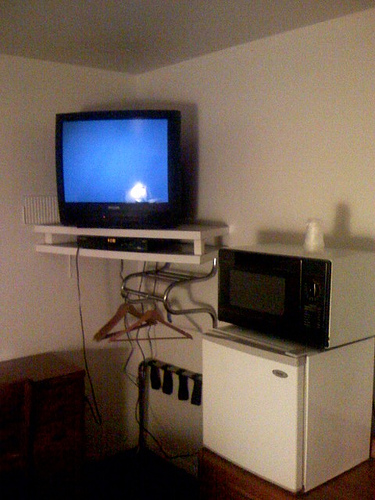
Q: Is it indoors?
A: Yes, it is indoors.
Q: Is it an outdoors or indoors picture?
A: It is indoors.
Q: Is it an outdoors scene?
A: No, it is indoors.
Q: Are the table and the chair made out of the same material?
A: Yes, both the table and the chair are made of wood.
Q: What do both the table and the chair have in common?
A: The material, both the table and the chair are wooden.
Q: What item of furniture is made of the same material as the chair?
A: The table is made of the same material as the chair.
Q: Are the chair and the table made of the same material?
A: Yes, both the chair and the table are made of wood.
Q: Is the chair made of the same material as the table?
A: Yes, both the chair and the table are made of wood.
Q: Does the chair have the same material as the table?
A: Yes, both the chair and the table are made of wood.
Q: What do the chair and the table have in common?
A: The material, both the chair and the table are wooden.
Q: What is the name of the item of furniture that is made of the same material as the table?
A: The piece of furniture is a chair.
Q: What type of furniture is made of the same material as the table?
A: The chair is made of the same material as the table.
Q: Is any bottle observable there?
A: No, there are no bottles.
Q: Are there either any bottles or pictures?
A: No, there are no bottles or pictures.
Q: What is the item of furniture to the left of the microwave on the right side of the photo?
A: The piece of furniture is a shelf.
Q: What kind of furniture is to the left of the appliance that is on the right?
A: The piece of furniture is a shelf.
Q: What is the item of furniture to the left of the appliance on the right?
A: The piece of furniture is a shelf.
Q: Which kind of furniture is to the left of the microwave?
A: The piece of furniture is a shelf.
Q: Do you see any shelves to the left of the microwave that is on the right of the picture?
A: Yes, there is a shelf to the left of the microwave.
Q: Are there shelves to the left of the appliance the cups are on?
A: Yes, there is a shelf to the left of the microwave.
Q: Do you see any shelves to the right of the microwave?
A: No, the shelf is to the left of the microwave.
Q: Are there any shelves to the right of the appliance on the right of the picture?
A: No, the shelf is to the left of the microwave.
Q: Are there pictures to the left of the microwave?
A: No, there is a shelf to the left of the microwave.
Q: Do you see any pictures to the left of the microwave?
A: No, there is a shelf to the left of the microwave.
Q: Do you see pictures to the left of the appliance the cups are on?
A: No, there is a shelf to the left of the microwave.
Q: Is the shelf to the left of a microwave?
A: Yes, the shelf is to the left of a microwave.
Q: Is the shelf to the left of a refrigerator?
A: No, the shelf is to the left of a microwave.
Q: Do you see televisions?
A: Yes, there is a television.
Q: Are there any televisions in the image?
A: Yes, there is a television.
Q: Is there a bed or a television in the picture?
A: Yes, there is a television.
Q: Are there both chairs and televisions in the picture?
A: Yes, there are both a television and a chair.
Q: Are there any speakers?
A: No, there are no speakers.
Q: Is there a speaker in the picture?
A: No, there are no speakers.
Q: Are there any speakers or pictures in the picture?
A: No, there are no speakers or pictures.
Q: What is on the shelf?
A: The television is on the shelf.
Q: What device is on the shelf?
A: The device is a television.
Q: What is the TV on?
A: The TV is on the shelf.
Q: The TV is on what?
A: The TV is on the shelf.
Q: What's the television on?
A: The TV is on the shelf.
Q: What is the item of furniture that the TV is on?
A: The piece of furniture is a shelf.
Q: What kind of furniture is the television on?
A: The TV is on the shelf.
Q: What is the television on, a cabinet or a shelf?
A: The television is on a shelf.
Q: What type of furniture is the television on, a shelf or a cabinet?
A: The television is on a shelf.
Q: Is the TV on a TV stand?
A: No, the TV is on the shelf.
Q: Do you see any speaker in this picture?
A: No, there are no speakers.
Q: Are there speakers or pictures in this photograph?
A: No, there are no speakers or pictures.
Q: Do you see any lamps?
A: No, there are no lamps.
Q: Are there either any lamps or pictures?
A: No, there are no lamps or pictures.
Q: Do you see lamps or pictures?
A: No, there are no lamps or pictures.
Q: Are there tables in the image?
A: Yes, there is a table.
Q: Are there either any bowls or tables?
A: Yes, there is a table.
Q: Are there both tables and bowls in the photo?
A: No, there is a table but no bowls.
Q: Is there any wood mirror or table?
A: Yes, there is a wood table.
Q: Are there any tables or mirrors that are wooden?
A: Yes, the table is wooden.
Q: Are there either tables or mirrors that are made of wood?
A: Yes, the table is made of wood.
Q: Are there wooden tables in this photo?
A: Yes, there is a wood table.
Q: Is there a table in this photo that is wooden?
A: Yes, there is a table that is wooden.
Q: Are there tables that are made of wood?
A: Yes, there is a table that is made of wood.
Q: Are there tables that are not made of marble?
A: Yes, there is a table that is made of wood.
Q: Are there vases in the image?
A: No, there are no vases.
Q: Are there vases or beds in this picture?
A: No, there are no vases or beds.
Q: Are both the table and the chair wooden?
A: Yes, both the table and the chair are wooden.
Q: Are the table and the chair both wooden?
A: Yes, both the table and the chair are wooden.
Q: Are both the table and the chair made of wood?
A: Yes, both the table and the chair are made of wood.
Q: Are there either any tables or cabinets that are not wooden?
A: No, there is a table but it is wooden.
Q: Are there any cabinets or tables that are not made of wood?
A: No, there is a table but it is made of wood.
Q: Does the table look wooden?
A: Yes, the table is wooden.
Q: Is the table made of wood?
A: Yes, the table is made of wood.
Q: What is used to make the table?
A: The table is made of wood.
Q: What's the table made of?
A: The table is made of wood.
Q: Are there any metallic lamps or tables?
A: No, there is a table but it is wooden.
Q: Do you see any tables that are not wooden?
A: No, there is a table but it is wooden.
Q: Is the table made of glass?
A: No, the table is made of wood.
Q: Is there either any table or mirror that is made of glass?
A: No, there is a table but it is made of wood.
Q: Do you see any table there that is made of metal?
A: No, there is a table but it is made of wood.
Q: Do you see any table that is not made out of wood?
A: No, there is a table but it is made of wood.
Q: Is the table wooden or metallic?
A: The table is wooden.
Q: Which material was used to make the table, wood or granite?
A: The table is made of wood.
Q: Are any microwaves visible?
A: Yes, there is a microwave.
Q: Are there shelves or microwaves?
A: Yes, there is a microwave.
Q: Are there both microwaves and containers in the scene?
A: No, there is a microwave but no containers.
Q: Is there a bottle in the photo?
A: No, there are no bottles.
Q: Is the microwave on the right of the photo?
A: Yes, the microwave is on the right of the image.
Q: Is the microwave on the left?
A: No, the microwave is on the right of the image.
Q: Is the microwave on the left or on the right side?
A: The microwave is on the right of the image.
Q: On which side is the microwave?
A: The microwave is on the right of the image.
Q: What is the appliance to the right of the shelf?
A: The appliance is a microwave.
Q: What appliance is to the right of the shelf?
A: The appliance is a microwave.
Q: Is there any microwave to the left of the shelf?
A: No, the microwave is to the right of the shelf.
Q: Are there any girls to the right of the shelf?
A: No, there is a microwave to the right of the shelf.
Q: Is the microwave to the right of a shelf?
A: Yes, the microwave is to the right of a shelf.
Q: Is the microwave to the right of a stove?
A: No, the microwave is to the right of a shelf.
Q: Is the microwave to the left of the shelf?
A: No, the microwave is to the right of the shelf.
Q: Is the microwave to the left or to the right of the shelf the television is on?
A: The microwave is to the right of the shelf.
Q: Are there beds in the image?
A: No, there are no beds.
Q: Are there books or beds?
A: No, there are no beds or books.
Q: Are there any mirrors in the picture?
A: No, there are no mirrors.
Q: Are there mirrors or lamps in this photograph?
A: No, there are no mirrors or lamps.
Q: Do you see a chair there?
A: Yes, there is a chair.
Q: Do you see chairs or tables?
A: Yes, there is a chair.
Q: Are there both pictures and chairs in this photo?
A: No, there is a chair but no pictures.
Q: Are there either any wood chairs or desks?
A: Yes, there is a wood chair.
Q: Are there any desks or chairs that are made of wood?
A: Yes, the chair is made of wood.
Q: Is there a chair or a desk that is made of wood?
A: Yes, the chair is made of wood.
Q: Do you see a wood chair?
A: Yes, there is a chair that is made of wood.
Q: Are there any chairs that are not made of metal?
A: Yes, there is a chair that is made of wood.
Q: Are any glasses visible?
A: No, there are no glasses.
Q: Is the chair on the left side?
A: Yes, the chair is on the left of the image.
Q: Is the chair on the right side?
A: No, the chair is on the left of the image.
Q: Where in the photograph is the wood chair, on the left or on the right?
A: The chair is on the left of the image.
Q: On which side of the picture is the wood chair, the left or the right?
A: The chair is on the left of the image.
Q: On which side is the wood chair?
A: The chair is on the left of the image.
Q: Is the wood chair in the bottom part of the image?
A: Yes, the chair is in the bottom of the image.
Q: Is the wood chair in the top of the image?
A: No, the chair is in the bottom of the image.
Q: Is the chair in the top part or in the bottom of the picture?
A: The chair is in the bottom of the image.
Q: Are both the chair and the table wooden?
A: Yes, both the chair and the table are wooden.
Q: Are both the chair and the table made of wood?
A: Yes, both the chair and the table are made of wood.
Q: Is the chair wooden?
A: Yes, the chair is wooden.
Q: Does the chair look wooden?
A: Yes, the chair is wooden.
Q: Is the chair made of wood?
A: Yes, the chair is made of wood.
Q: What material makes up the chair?
A: The chair is made of wood.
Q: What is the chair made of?
A: The chair is made of wood.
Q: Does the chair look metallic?
A: No, the chair is wooden.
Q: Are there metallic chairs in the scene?
A: No, there is a chair but it is wooden.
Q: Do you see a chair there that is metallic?
A: No, there is a chair but it is wooden.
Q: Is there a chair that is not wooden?
A: No, there is a chair but it is wooden.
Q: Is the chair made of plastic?
A: No, the chair is made of wood.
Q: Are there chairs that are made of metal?
A: No, there is a chair but it is made of wood.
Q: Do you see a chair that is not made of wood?
A: No, there is a chair but it is made of wood.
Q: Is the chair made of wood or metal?
A: The chair is made of wood.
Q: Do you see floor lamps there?
A: No, there are no floor lamps.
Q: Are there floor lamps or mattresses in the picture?
A: No, there are no floor lamps or mattresses.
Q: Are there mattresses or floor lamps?
A: No, there are no floor lamps or mattresses.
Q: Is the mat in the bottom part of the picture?
A: Yes, the mat is in the bottom of the image.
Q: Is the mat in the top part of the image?
A: No, the mat is in the bottom of the image.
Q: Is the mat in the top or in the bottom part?
A: The mat is in the bottom of the image.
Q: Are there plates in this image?
A: No, there are no plates.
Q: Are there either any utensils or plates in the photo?
A: No, there are no plates or utensils.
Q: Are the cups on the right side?
A: Yes, the cups are on the right of the image.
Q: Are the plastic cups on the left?
A: No, the cups are on the right of the image.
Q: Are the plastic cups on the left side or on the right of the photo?
A: The cups are on the right of the image.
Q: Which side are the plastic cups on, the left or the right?
A: The cups are on the right of the image.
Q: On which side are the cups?
A: The cups are on the right of the image.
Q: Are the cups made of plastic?
A: Yes, the cups are made of plastic.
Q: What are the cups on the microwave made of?
A: The cups are made of plastic.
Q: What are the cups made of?
A: The cups are made of plastic.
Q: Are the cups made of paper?
A: No, the cups are made of plastic.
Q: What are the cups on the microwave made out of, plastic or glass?
A: The cups are made of plastic.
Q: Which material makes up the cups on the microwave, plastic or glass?
A: The cups are made of plastic.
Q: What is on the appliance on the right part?
A: The cups are on the microwave.